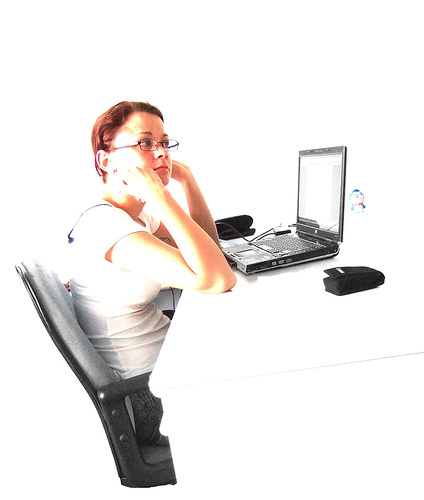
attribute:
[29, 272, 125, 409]
chair — office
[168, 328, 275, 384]
desk — white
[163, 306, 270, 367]
desk — white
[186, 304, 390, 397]
desk — white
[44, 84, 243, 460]
girl — sitting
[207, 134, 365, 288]
laptop — open, black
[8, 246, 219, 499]
chair — black, grey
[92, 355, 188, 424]
arm — black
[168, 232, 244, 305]
elbow — bent, resting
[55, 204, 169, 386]
shirt — white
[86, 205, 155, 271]
sleeve — short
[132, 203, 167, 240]
sleeve — short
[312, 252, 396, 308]
case — black, sitting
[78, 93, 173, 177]
hair — red, short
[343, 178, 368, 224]
penguin — black, small, white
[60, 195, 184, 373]
blouse — white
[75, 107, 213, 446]
woman — young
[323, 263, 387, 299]
cell phone — black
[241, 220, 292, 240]
cords — electronic